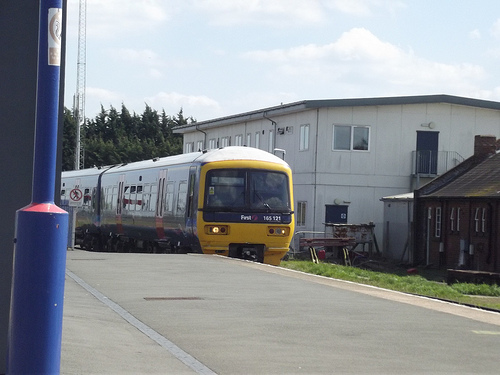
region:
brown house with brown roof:
[403, 140, 496, 262]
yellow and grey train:
[53, 137, 306, 273]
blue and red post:
[0, 6, 88, 371]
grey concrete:
[98, 244, 241, 372]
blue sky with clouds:
[151, 11, 451, 108]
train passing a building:
[83, 90, 362, 285]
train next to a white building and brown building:
[184, 66, 494, 285]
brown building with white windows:
[418, 163, 495, 245]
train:
[104, 143, 301, 275]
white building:
[243, 71, 478, 260]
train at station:
[55, 143, 305, 267]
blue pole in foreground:
[12, 2, 66, 371]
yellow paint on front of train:
[195, 149, 300, 260]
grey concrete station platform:
[70, 243, 480, 373]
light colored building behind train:
[172, 83, 488, 239]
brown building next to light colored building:
[418, 168, 498, 298]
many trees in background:
[53, 101, 196, 157]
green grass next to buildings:
[292, 233, 499, 309]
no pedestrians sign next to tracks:
[65, 183, 88, 212]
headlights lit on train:
[205, 221, 292, 238]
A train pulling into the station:
[121, 138, 299, 260]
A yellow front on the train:
[184, 142, 312, 256]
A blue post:
[10, 2, 89, 279]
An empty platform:
[131, 252, 370, 365]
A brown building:
[409, 133, 499, 281]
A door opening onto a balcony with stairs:
[407, 116, 468, 175]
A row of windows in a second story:
[180, 120, 316, 157]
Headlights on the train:
[196, 219, 301, 239]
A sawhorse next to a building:
[297, 230, 367, 271]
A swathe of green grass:
[341, 256, 449, 297]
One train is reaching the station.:
[100, 156, 292, 246]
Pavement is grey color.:
[201, 306, 366, 358]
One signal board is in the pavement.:
[61, 178, 88, 219]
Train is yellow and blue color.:
[107, 168, 259, 238]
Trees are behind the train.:
[80, 121, 172, 152]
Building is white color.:
[305, 126, 412, 184]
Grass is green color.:
[357, 261, 450, 303]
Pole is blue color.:
[13, 111, 69, 369]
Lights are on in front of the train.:
[199, 206, 297, 246]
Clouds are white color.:
[135, 13, 332, 84]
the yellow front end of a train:
[200, 148, 288, 259]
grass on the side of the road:
[326, 260, 370, 279]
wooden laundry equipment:
[302, 212, 388, 258]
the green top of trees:
[94, 112, 184, 157]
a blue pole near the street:
[19, 10, 71, 367]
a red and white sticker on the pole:
[49, 7, 60, 66]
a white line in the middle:
[96, 291, 136, 316]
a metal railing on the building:
[415, 147, 456, 175]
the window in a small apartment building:
[331, 116, 383, 159]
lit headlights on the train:
[203, 217, 290, 235]